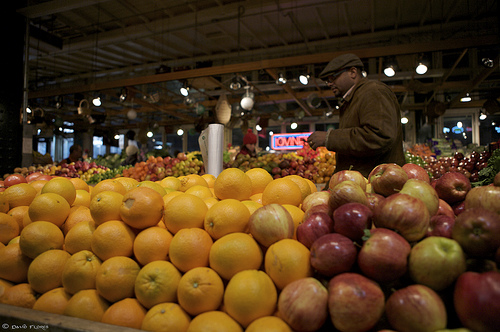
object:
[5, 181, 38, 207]
oranges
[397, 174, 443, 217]
apples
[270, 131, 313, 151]
neon sign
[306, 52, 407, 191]
man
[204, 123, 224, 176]
plastic bags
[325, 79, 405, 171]
jacket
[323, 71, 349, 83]
glasses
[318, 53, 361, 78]
hat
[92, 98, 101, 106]
light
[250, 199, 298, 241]
fruits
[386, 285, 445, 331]
apple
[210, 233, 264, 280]
orange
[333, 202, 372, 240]
apple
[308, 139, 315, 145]
ring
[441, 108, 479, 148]
window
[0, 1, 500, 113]
ceiling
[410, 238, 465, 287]
apple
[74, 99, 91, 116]
basket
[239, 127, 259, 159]
woman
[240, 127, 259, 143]
beanie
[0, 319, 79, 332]
copyright symbol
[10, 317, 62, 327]
photographer's name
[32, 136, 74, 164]
window